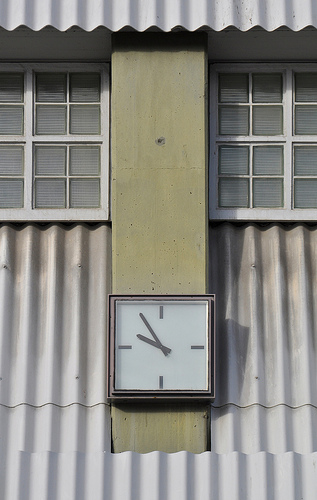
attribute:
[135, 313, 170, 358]
hands —  black, black, clock's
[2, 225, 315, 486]
tin — white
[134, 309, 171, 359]
hands — black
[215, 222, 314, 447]
panels — alluminum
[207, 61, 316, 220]
window frame — white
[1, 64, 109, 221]
window — small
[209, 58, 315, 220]
window — small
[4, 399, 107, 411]
seam — of tin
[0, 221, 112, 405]
metal — siding 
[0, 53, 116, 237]
window — white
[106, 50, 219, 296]
pillar — gray.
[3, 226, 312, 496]
siding — white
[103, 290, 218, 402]
frame — white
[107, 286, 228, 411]
clock — square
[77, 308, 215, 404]
clock — square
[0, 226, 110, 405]
tin — pieces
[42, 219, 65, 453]
ridges — vertical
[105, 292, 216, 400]
clock — square,  white,  time, silver, white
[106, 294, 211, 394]
clock — plain ,  square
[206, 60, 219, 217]
frame — white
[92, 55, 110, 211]
frame — white